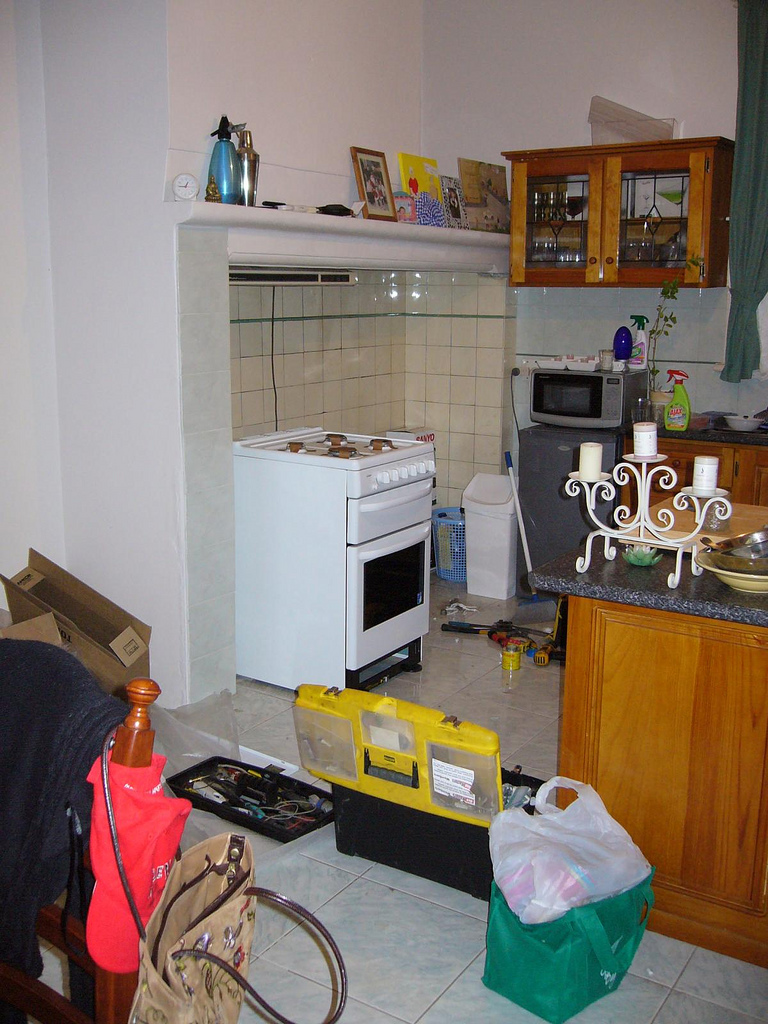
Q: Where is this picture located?
A: In a kitchen.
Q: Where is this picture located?
A: The kitchen.